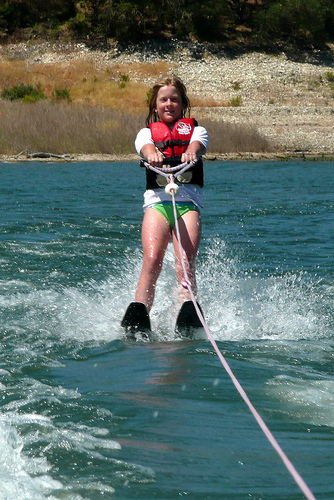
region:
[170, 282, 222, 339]
left foot of skiier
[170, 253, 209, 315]
left leg of girl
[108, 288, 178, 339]
right foot of girl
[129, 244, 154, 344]
right leg of woman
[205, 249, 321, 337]
splashing waves on water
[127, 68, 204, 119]
head of the woman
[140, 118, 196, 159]
red vest on woman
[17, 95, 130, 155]
grass behind the water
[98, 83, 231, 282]
woman water skiing in water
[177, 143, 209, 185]
left hand of woman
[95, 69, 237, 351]
A girl on water skis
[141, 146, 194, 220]
hands holding a rope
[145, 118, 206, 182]
a red life vest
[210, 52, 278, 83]
small gravels on the shore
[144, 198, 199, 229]
green swimming trunks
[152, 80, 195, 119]
The head of a young girl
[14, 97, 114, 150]
died grass on the shore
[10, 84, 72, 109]
Green bushes on the shore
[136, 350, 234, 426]
clear blue water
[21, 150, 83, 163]
A piece of draft wood on the shore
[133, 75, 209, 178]
girl in red lifejacket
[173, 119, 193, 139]
a white symbol on life jacket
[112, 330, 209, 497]
shadow of water skier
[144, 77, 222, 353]
water skier holding on to ropes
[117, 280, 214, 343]
person using black water skiis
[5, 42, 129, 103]
hillside with green and brown grass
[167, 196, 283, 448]
rope pulling water skier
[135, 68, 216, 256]
smiling female water skier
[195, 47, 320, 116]
rocking hillside next to lake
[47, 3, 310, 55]
trees next to hilly cliffside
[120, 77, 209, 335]
Young girl using water skis on body of water.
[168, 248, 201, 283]
left leg of girl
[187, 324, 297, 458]
rope of water ski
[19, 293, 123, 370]
white waves on water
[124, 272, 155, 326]
right leg of girl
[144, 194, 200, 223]
green bikini on girl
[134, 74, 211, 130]
face of little girl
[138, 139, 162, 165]
right hand of girl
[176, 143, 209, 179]
left hand of girl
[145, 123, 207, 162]
red safety vest on girl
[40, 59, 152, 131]
grassy hill in back